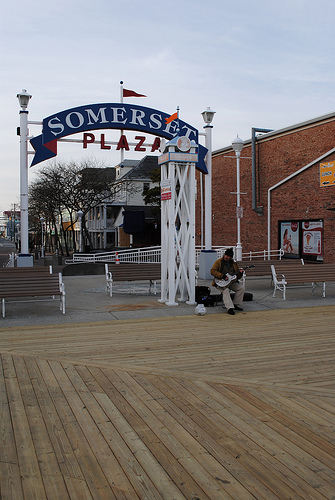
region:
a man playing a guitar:
[209, 243, 250, 307]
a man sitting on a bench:
[199, 237, 248, 321]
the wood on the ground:
[10, 328, 282, 496]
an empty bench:
[4, 267, 74, 313]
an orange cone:
[115, 252, 121, 266]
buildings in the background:
[78, 148, 334, 246]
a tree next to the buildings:
[38, 167, 95, 253]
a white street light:
[227, 130, 244, 255]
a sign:
[41, 100, 244, 186]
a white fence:
[82, 247, 180, 262]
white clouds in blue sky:
[245, 31, 274, 56]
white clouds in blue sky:
[198, 34, 229, 60]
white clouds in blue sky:
[174, 41, 219, 76]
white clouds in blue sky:
[120, 6, 153, 39]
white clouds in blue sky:
[96, 28, 153, 61]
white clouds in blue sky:
[64, 3, 127, 67]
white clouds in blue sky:
[263, 25, 309, 72]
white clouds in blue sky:
[204, 22, 249, 49]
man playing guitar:
[207, 245, 254, 313]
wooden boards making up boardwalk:
[21, 354, 257, 496]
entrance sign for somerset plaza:
[9, 76, 219, 177]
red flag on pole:
[119, 79, 152, 104]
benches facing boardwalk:
[0, 262, 71, 316]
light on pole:
[229, 135, 245, 235]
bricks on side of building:
[269, 147, 302, 166]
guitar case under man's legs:
[207, 293, 255, 301]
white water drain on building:
[264, 147, 315, 213]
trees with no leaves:
[29, 175, 84, 256]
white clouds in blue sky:
[148, 20, 241, 55]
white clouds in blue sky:
[250, 55, 277, 90]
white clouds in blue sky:
[171, 38, 221, 63]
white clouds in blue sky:
[62, 25, 82, 39]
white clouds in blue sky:
[260, 80, 287, 111]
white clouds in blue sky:
[151, 42, 191, 85]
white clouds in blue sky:
[76, 15, 113, 36]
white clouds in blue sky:
[46, 11, 91, 61]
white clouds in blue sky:
[168, 7, 209, 58]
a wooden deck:
[143, 393, 254, 459]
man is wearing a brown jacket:
[213, 258, 225, 272]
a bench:
[3, 275, 62, 294]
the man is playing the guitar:
[213, 270, 235, 287]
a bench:
[279, 264, 334, 279]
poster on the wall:
[280, 222, 321, 257]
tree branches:
[39, 173, 74, 195]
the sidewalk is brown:
[109, 300, 155, 312]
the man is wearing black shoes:
[226, 306, 234, 315]